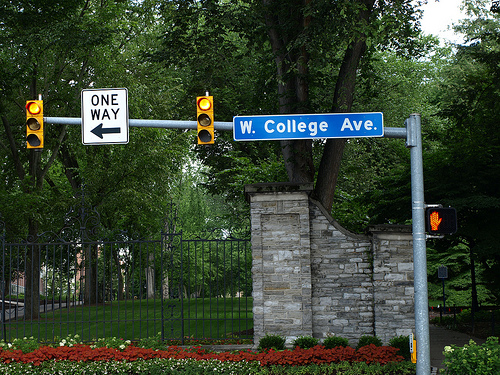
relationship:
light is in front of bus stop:
[196, 96, 214, 145] [399, 111, 421, 371]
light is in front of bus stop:
[26, 100, 44, 150] [399, 111, 421, 371]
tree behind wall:
[230, 9, 365, 217] [196, 183, 433, 370]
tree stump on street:
[359, 341, 402, 362] [425, 315, 495, 372]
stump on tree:
[86, 298, 106, 305] [4, 0, 184, 307]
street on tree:
[1, 297, 81, 325] [6, 7, 75, 313]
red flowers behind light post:
[3, 339, 403, 368] [17, 81, 449, 373]